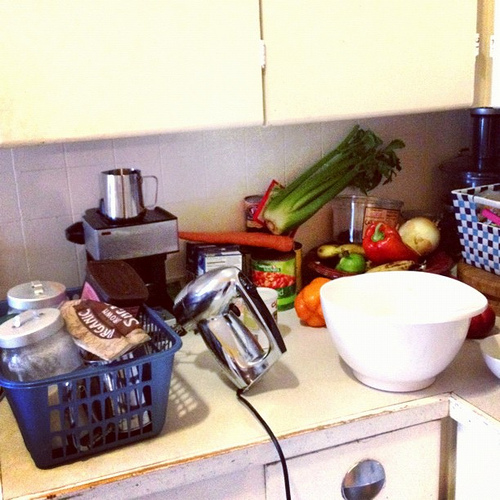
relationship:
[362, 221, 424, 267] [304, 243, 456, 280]
pepper inside of bowl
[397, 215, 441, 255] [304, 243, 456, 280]
onion inside of bowl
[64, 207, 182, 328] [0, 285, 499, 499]
coffee maker on top of counter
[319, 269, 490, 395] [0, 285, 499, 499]
bowl on top of counter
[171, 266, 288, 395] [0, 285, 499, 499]
mixer on top of counter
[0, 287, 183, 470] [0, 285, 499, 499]
basket on top of counter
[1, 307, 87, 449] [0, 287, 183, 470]
jar inside of basket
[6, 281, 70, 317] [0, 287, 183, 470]
jar inside of basket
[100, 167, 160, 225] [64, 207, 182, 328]
coffee mug on top of coffee maker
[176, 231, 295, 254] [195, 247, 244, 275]
carrot on top of box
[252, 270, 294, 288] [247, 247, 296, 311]
tomatoes inside of can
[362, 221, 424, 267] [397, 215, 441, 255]
pepper next to onion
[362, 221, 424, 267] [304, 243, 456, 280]
pepper sitting in bowl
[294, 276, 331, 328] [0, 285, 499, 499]
pepper on top of counter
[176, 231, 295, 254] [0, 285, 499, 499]
carrot on top of counter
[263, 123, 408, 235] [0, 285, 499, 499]
vegetable on top of counter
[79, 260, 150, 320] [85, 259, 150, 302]
container has lid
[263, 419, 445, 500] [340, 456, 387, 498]
drawer has handle